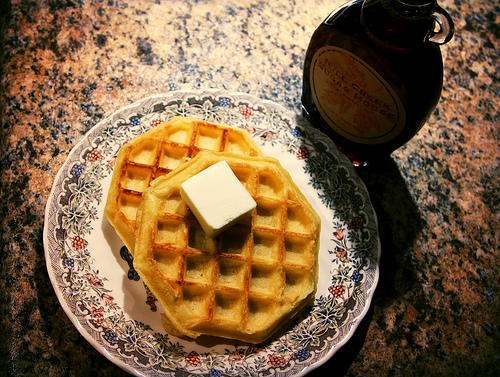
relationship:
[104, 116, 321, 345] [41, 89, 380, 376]
waffle sitting on plate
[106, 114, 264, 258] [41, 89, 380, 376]
waffle sitting on plate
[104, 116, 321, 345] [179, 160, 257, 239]
waffle with butter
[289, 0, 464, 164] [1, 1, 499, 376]
bottle sitting on surface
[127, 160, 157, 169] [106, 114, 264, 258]
burned bit burnt onto waffle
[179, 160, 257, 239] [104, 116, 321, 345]
butter atop waffle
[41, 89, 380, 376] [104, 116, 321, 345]
plate with waffle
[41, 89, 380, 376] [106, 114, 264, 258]
plate with waffle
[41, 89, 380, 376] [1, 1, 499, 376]
plate sitting on surface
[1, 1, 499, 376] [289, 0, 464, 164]
surface with bottle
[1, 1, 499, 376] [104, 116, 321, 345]
surface with waffle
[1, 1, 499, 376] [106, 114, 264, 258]
surface with waffle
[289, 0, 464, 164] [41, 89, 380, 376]
bottle next to plate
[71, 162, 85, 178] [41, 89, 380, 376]
berry design painted on plate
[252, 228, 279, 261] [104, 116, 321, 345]
square marked in waffle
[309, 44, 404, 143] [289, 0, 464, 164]
sticker stuck on bottle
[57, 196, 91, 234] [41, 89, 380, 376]
leaf design painted on plate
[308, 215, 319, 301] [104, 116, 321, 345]
edge of waffle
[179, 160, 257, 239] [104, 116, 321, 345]
butter sitting on waffle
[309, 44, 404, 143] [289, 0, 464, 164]
label placed on bottle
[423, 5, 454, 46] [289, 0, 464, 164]
glass handle of bottle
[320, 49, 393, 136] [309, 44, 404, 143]
orange leaf drawn on sticker